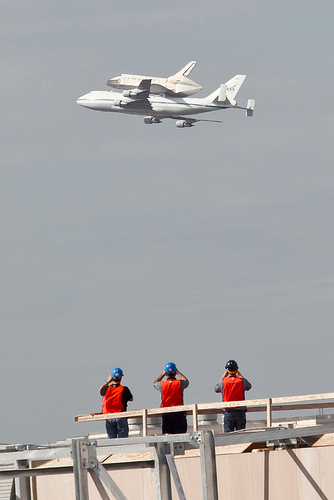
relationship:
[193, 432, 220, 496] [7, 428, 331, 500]
post against wall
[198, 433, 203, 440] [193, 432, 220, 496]
stud in post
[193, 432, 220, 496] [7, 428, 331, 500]
post in surface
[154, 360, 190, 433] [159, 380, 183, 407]
man wearing shirt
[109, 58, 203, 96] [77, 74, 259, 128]
space shuttle atop jumbo jet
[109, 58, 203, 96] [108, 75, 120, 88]
space shuttle has nose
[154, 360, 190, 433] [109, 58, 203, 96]
man watching space shuttle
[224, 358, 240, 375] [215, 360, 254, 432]
hardhat on man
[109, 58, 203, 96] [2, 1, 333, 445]
space shuttle in sky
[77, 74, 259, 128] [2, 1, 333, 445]
jumbo jet in sky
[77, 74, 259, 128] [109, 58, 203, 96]
jumbo jet next to space shuttle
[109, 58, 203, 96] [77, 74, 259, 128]
space shuttle on jumbo jet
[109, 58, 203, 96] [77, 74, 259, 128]
space shuttle carried on back of jumbo jet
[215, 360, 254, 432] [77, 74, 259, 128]
man watching jumbo jet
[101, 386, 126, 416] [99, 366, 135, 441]
vest on man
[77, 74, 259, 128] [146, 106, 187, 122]
jumbo jet has landing gear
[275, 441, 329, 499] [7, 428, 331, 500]
shadow on wall